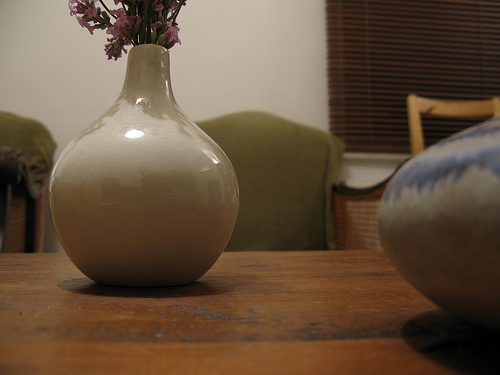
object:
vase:
[48, 43, 240, 292]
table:
[0, 253, 499, 375]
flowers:
[163, 16, 182, 48]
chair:
[186, 108, 345, 251]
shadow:
[56, 275, 232, 299]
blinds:
[328, 0, 500, 154]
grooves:
[43, 320, 400, 350]